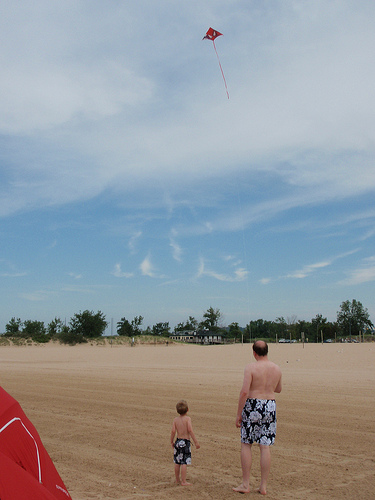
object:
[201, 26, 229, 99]
kite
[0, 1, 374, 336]
sky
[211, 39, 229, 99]
string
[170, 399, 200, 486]
boy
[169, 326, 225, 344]
beach house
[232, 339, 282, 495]
man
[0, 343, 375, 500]
sand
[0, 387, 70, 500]
tent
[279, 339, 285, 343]
car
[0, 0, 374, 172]
cloud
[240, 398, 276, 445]
shorts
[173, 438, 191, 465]
shorts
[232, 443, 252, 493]
leg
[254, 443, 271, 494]
leg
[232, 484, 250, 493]
foot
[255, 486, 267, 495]
foot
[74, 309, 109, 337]
tree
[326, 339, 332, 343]
car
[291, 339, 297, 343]
car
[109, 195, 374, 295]
cloud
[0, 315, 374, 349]
shoreline